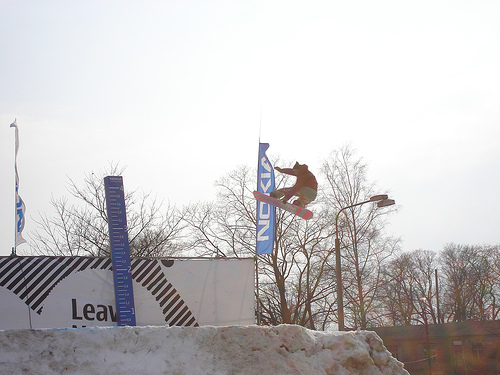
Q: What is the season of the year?
A: Winter.